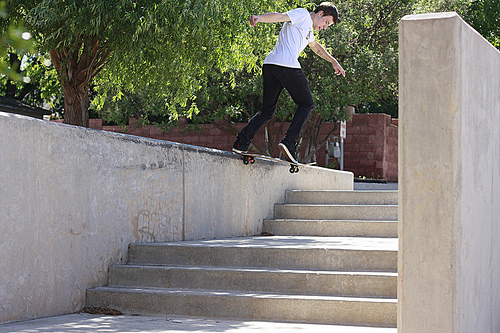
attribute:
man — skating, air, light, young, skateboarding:
[257, 13, 369, 210]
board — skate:
[235, 149, 324, 185]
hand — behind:
[233, 16, 297, 20]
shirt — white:
[273, 12, 313, 83]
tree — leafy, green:
[96, 9, 245, 100]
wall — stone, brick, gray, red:
[323, 103, 419, 186]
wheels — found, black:
[242, 153, 297, 183]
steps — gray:
[280, 200, 388, 255]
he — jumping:
[257, 17, 342, 152]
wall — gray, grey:
[121, 166, 176, 231]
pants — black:
[240, 68, 317, 154]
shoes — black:
[231, 142, 320, 164]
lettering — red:
[336, 123, 355, 148]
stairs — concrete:
[268, 190, 377, 246]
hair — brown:
[317, 8, 343, 27]